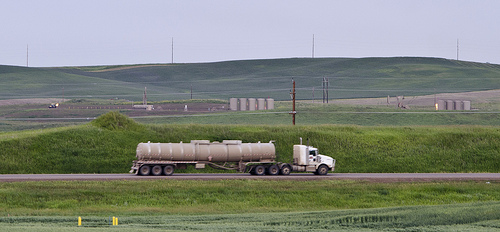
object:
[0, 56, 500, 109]
hills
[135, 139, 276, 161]
tank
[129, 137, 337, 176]
18 wheeler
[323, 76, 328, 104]
wires poles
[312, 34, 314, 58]
pole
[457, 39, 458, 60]
pole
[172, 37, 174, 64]
pole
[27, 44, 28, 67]
pole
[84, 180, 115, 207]
grass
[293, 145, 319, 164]
cab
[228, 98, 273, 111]
barrels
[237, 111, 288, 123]
ground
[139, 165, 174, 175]
wheels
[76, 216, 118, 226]
markers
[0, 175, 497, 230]
ground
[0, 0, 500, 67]
sky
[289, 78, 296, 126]
pole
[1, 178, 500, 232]
field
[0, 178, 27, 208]
grass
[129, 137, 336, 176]
trailer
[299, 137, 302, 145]
pipe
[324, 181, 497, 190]
grass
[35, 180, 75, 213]
grass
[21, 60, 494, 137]
distance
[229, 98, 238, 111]
pipes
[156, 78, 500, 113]
field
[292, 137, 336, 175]
tractor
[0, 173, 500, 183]
road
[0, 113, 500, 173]
field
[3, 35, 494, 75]
distance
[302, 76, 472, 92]
wires